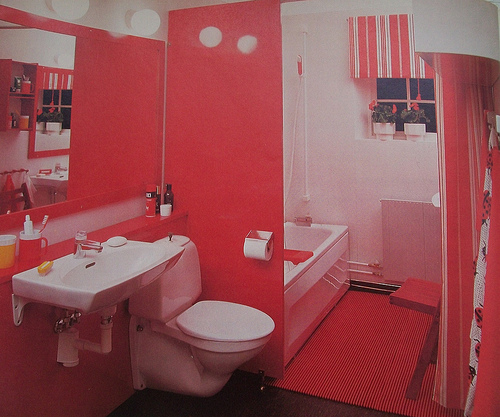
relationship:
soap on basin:
[104, 224, 125, 246] [66, 243, 151, 306]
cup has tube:
[15, 236, 44, 266] [19, 212, 37, 232]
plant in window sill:
[355, 86, 439, 145] [339, 91, 453, 168]